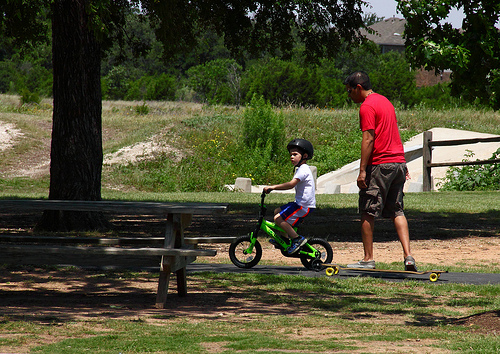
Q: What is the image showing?
A: It is showing a park.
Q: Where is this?
A: This is at the park.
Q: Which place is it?
A: It is a park.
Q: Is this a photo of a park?
A: Yes, it is showing a park.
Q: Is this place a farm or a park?
A: It is a park.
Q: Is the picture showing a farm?
A: No, the picture is showing a park.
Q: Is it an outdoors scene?
A: Yes, it is outdoors.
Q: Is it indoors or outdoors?
A: It is outdoors.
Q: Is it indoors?
A: No, it is outdoors.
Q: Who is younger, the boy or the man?
A: The boy is younger than the man.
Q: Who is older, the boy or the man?
A: The man is older than the boy.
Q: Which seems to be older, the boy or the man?
A: The man is older than the boy.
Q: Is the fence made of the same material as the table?
A: Yes, both the fence and the table are made of wood.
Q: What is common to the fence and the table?
A: The material, both the fence and the table are wooden.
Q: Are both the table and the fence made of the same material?
A: Yes, both the table and the fence are made of wood.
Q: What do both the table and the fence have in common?
A: The material, both the table and the fence are wooden.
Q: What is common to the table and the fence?
A: The material, both the table and the fence are wooden.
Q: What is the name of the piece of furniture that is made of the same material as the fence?
A: The piece of furniture is a table.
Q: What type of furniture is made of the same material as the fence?
A: The table is made of the same material as the fence.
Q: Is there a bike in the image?
A: Yes, there is a bike.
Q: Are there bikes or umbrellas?
A: Yes, there is a bike.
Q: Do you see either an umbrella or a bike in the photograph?
A: Yes, there is a bike.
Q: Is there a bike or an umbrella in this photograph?
A: Yes, there is a bike.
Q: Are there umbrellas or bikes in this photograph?
A: Yes, there is a bike.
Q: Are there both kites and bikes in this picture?
A: No, there is a bike but no kites.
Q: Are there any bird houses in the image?
A: No, there are no bird houses.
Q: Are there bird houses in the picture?
A: No, there are no bird houses.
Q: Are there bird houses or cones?
A: No, there are no bird houses or cones.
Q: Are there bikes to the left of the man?
A: Yes, there is a bike to the left of the man.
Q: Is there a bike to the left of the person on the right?
A: Yes, there is a bike to the left of the man.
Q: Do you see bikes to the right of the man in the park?
A: No, the bike is to the left of the man.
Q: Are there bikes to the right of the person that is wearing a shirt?
A: No, the bike is to the left of the man.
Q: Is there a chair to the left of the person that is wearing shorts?
A: No, there is a bike to the left of the man.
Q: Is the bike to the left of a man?
A: Yes, the bike is to the left of a man.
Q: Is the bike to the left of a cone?
A: No, the bike is to the left of a man.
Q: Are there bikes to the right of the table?
A: Yes, there is a bike to the right of the table.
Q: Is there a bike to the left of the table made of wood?
A: No, the bike is to the right of the table.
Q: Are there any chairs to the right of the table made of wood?
A: No, there is a bike to the right of the table.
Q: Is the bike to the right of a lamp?
A: No, the bike is to the right of the table.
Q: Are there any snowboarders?
A: No, there are no snowboarders.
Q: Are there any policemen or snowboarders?
A: No, there are no snowboarders or policemen.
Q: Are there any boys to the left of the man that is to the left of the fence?
A: Yes, there is a boy to the left of the man.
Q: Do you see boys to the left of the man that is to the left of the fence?
A: Yes, there is a boy to the left of the man.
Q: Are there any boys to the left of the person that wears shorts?
A: Yes, there is a boy to the left of the man.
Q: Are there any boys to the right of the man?
A: No, the boy is to the left of the man.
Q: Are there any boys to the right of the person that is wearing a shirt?
A: No, the boy is to the left of the man.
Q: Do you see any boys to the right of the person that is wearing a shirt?
A: No, the boy is to the left of the man.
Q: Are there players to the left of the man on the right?
A: No, there is a boy to the left of the man.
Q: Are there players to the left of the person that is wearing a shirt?
A: No, there is a boy to the left of the man.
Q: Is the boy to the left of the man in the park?
A: Yes, the boy is to the left of the man.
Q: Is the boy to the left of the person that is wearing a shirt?
A: Yes, the boy is to the left of the man.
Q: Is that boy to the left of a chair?
A: No, the boy is to the left of the man.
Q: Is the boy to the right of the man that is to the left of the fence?
A: No, the boy is to the left of the man.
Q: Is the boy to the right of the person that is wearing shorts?
A: No, the boy is to the left of the man.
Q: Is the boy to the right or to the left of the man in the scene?
A: The boy is to the left of the man.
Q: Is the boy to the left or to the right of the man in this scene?
A: The boy is to the left of the man.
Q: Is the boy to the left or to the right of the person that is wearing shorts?
A: The boy is to the left of the man.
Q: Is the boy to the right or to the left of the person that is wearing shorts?
A: The boy is to the left of the man.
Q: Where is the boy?
A: The boy is in the park.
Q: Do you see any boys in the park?
A: Yes, there is a boy in the park.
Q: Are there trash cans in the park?
A: No, there is a boy in the park.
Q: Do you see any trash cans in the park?
A: No, there is a boy in the park.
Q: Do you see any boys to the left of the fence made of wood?
A: Yes, there is a boy to the left of the fence.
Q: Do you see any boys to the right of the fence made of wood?
A: No, the boy is to the left of the fence.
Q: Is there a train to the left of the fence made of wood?
A: No, there is a boy to the left of the fence.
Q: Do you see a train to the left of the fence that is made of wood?
A: No, there is a boy to the left of the fence.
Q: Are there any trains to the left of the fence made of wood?
A: No, there is a boy to the left of the fence.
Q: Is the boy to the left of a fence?
A: Yes, the boy is to the left of a fence.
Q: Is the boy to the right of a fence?
A: No, the boy is to the left of a fence.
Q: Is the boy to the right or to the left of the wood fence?
A: The boy is to the left of the fence.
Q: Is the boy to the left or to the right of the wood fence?
A: The boy is to the left of the fence.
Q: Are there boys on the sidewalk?
A: Yes, there is a boy on the sidewalk.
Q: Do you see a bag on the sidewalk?
A: No, there is a boy on the sidewalk.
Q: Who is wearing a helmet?
A: The boy is wearing a helmet.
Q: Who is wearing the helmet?
A: The boy is wearing a helmet.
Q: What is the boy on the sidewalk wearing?
A: The boy is wearing a helmet.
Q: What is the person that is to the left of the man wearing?
A: The boy is wearing a helmet.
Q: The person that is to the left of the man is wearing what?
A: The boy is wearing a helmet.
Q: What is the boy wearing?
A: The boy is wearing a helmet.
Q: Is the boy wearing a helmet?
A: Yes, the boy is wearing a helmet.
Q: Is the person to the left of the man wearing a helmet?
A: Yes, the boy is wearing a helmet.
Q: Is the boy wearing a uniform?
A: No, the boy is wearing a helmet.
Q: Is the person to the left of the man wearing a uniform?
A: No, the boy is wearing a helmet.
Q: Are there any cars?
A: No, there are no cars.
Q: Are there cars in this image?
A: No, there are no cars.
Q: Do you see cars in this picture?
A: No, there are no cars.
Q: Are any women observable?
A: No, there are no women.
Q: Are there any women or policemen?
A: No, there are no women or policemen.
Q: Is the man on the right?
A: Yes, the man is on the right of the image.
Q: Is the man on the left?
A: No, the man is on the right of the image.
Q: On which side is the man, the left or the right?
A: The man is on the right of the image.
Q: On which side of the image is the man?
A: The man is on the right of the image.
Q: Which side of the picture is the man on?
A: The man is on the right of the image.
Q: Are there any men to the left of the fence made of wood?
A: Yes, there is a man to the left of the fence.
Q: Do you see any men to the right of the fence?
A: No, the man is to the left of the fence.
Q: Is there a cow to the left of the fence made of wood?
A: No, there is a man to the left of the fence.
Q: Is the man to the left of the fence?
A: Yes, the man is to the left of the fence.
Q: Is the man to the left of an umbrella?
A: No, the man is to the left of the fence.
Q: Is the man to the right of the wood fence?
A: No, the man is to the left of the fence.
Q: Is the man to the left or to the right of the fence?
A: The man is to the left of the fence.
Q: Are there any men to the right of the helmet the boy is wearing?
A: Yes, there is a man to the right of the helmet.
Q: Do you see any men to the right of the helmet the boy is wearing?
A: Yes, there is a man to the right of the helmet.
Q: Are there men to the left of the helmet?
A: No, the man is to the right of the helmet.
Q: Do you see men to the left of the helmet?
A: No, the man is to the right of the helmet.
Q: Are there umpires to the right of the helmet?
A: No, there is a man to the right of the helmet.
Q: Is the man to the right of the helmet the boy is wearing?
A: Yes, the man is to the right of the helmet.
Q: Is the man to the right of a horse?
A: No, the man is to the right of the helmet.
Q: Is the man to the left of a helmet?
A: No, the man is to the right of a helmet.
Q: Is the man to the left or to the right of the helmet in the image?
A: The man is to the right of the helmet.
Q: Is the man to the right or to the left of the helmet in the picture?
A: The man is to the right of the helmet.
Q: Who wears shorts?
A: The man wears shorts.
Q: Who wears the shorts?
A: The man wears shorts.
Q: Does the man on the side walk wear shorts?
A: Yes, the man wears shorts.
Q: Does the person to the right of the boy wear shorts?
A: Yes, the man wears shorts.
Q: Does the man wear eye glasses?
A: No, the man wears shorts.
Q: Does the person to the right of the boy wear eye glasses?
A: No, the man wears shorts.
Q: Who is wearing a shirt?
A: The man is wearing a shirt.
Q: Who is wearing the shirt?
A: The man is wearing a shirt.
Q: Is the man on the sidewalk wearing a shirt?
A: Yes, the man is wearing a shirt.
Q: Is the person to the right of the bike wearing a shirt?
A: Yes, the man is wearing a shirt.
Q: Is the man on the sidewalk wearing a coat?
A: No, the man is wearing a shirt.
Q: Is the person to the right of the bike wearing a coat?
A: No, the man is wearing a shirt.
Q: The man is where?
A: The man is in the park.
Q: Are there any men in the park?
A: Yes, there is a man in the park.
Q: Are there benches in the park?
A: No, there is a man in the park.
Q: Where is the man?
A: The man is on the sidewalk.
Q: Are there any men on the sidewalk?
A: Yes, there is a man on the sidewalk.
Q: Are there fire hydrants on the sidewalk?
A: No, there is a man on the sidewalk.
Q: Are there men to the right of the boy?
A: Yes, there is a man to the right of the boy.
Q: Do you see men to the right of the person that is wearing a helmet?
A: Yes, there is a man to the right of the boy.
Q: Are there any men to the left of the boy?
A: No, the man is to the right of the boy.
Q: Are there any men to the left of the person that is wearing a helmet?
A: No, the man is to the right of the boy.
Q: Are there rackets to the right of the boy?
A: No, there is a man to the right of the boy.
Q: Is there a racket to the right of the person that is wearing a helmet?
A: No, there is a man to the right of the boy.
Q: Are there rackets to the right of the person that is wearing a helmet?
A: No, there is a man to the right of the boy.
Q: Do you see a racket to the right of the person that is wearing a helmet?
A: No, there is a man to the right of the boy.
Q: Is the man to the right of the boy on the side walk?
A: Yes, the man is to the right of the boy.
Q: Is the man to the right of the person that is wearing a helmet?
A: Yes, the man is to the right of the boy.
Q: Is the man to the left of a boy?
A: No, the man is to the right of a boy.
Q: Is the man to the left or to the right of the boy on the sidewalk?
A: The man is to the right of the boy.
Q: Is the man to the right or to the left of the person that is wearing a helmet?
A: The man is to the right of the boy.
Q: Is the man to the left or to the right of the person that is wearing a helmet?
A: The man is to the right of the boy.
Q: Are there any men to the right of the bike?
A: Yes, there is a man to the right of the bike.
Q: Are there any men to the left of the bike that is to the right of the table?
A: No, the man is to the right of the bike.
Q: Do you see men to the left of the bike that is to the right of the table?
A: No, the man is to the right of the bike.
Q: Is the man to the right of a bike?
A: Yes, the man is to the right of a bike.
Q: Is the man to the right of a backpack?
A: No, the man is to the right of a bike.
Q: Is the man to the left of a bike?
A: No, the man is to the right of a bike.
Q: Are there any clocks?
A: No, there are no clocks.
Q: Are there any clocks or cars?
A: No, there are no clocks or cars.